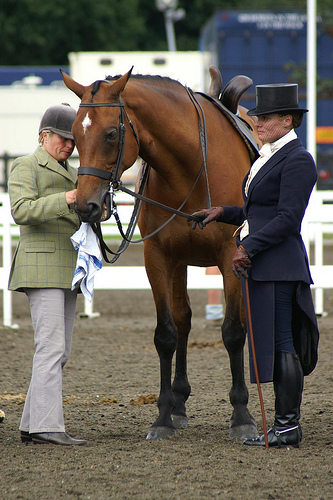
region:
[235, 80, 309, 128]
black top hat on head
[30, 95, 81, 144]
black horse riding hat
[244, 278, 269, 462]
long brown cane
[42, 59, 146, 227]
brown large head of horse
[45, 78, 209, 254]
ropes around the head of horse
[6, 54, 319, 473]
two people standing next to a horse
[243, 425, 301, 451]
black shoes on feet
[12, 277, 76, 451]
tan horse riding pants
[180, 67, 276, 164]
black saddle on the top of a horse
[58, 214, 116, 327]
blue and white towel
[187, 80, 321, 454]
the woman dressed in all blue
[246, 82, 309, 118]
the black top hat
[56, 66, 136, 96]
the horses two ears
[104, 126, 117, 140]
the horses left eye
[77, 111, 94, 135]
the white spot on the horses head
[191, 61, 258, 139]
the saddle on the horse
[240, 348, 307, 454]
the knee high black boots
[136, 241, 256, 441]
the horse's legs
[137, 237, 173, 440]
the horse's front right leg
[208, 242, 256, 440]
the horse's front left leg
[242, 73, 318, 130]
A black hat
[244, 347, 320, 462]
a pair of black boots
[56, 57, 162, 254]
the horses head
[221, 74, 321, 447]
the woman is standing next to the horse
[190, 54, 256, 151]
a portion of the saddle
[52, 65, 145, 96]
the horses ears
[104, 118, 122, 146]
the horses eye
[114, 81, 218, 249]
the reins are black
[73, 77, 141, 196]
this is the horses bridle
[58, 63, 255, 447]
the horse is chestnut brown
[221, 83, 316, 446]
a woman in a riding suit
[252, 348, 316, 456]
pair of black boots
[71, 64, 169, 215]
a horses head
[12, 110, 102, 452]
a woman working on a horse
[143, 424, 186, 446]
A horses foot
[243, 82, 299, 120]
a womans hat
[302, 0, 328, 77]
a white pole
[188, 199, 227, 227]
a womans gloved hand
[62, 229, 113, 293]
a blue and white towel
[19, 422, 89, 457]
brown boots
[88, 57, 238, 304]
brown colored race horse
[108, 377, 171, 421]
horse dung on the ground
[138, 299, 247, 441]
black fur on horse legs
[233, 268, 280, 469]
brown stick held by woman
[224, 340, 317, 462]
black leather riding boots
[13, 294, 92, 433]
tan colored riding pants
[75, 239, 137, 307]
blue and white rag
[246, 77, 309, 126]
black top hat on woman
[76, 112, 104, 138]
white diamond shape on horse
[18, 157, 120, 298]
green and blue plaid jacket